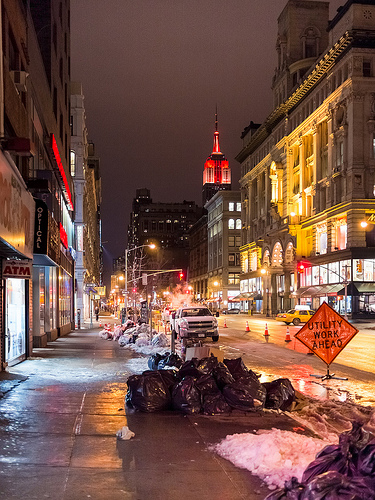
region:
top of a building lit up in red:
[202, 102, 233, 185]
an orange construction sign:
[296, 299, 359, 385]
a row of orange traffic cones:
[181, 316, 321, 357]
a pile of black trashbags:
[127, 347, 301, 412]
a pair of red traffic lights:
[162, 259, 311, 284]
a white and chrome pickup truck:
[167, 306, 219, 341]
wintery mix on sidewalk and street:
[107, 310, 371, 490]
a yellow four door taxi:
[274, 300, 329, 327]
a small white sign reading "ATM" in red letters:
[1, 262, 34, 279]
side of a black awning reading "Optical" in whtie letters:
[33, 199, 47, 253]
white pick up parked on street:
[166, 298, 227, 340]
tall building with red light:
[198, 93, 232, 203]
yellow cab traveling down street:
[276, 294, 318, 330]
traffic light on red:
[296, 260, 308, 277]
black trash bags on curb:
[114, 340, 294, 418]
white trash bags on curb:
[97, 311, 168, 354]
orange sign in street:
[292, 296, 353, 382]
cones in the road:
[222, 313, 295, 347]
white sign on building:
[3, 257, 32, 280]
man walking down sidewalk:
[90, 301, 103, 320]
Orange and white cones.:
[216, 315, 291, 341]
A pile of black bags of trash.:
[123, 347, 294, 412]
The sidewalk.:
[0, 304, 321, 494]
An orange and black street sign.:
[292, 300, 355, 377]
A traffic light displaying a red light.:
[294, 260, 302, 271]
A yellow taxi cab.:
[274, 303, 313, 322]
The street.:
[165, 297, 369, 413]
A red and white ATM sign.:
[1, 261, 31, 276]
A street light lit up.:
[123, 240, 153, 309]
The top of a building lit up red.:
[202, 104, 233, 192]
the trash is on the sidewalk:
[124, 352, 296, 415]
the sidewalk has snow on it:
[215, 426, 337, 488]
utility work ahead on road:
[294, 299, 360, 384]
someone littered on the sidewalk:
[116, 423, 135, 441]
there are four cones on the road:
[220, 320, 293, 343]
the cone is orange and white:
[283, 323, 293, 342]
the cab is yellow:
[274, 308, 321, 325]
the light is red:
[299, 262, 304, 274]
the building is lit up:
[203, 101, 231, 203]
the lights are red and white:
[201, 101, 232, 201]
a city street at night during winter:
[25, 134, 361, 488]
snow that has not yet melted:
[207, 417, 324, 480]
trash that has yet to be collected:
[125, 348, 294, 417]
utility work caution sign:
[295, 301, 353, 380]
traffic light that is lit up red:
[296, 256, 354, 300]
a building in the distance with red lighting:
[190, 101, 232, 185]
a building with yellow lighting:
[233, 119, 367, 295]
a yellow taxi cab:
[273, 299, 320, 325]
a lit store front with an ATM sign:
[2, 247, 35, 368]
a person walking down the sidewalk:
[93, 299, 103, 324]